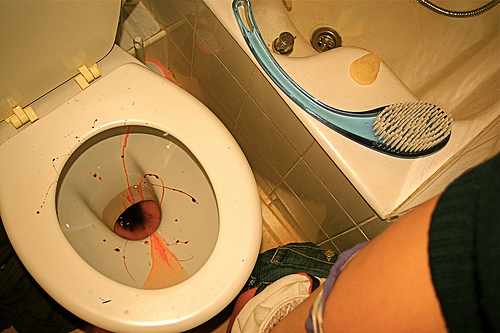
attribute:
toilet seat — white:
[215, 178, 251, 238]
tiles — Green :
[231, 68, 314, 151]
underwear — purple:
[303, 237, 371, 331]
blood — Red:
[114, 202, 148, 233]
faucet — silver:
[276, 14, 350, 61]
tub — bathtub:
[278, 7, 456, 121]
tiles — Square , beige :
[127, 0, 401, 266]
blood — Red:
[109, 170, 199, 268]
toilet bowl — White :
[21, 112, 268, 313]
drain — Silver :
[274, 20, 342, 52]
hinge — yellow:
[9, 97, 40, 139]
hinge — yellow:
[72, 52, 101, 88]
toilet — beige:
[1, 40, 231, 312]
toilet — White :
[18, 124, 262, 312]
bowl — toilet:
[0, 46, 265, 324]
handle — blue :
[230, 0, 372, 147]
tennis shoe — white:
[231, 270, 328, 330]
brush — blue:
[238, 5, 459, 158]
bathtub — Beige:
[141, 0, 498, 260]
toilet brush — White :
[132, 32, 167, 79]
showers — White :
[360, 28, 492, 185]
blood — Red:
[80, 127, 198, 289]